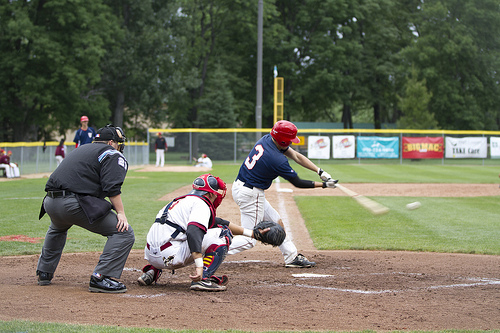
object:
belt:
[43, 182, 75, 199]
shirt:
[144, 192, 213, 253]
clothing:
[37, 143, 135, 276]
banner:
[445, 135, 488, 162]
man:
[37, 126, 132, 294]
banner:
[331, 135, 356, 160]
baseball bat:
[329, 178, 389, 215]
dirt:
[2, 245, 498, 330]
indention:
[235, 290, 293, 312]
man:
[225, 120, 340, 269]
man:
[72, 115, 99, 147]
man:
[153, 133, 169, 168]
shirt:
[73, 124, 104, 145]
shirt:
[153, 138, 169, 148]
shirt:
[43, 140, 130, 198]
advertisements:
[307, 134, 490, 161]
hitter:
[233, 119, 335, 270]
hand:
[321, 179, 338, 188]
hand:
[321, 170, 336, 183]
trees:
[3, 0, 244, 131]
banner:
[401, 137, 442, 161]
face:
[212, 183, 227, 203]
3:
[244, 141, 264, 170]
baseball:
[408, 200, 422, 210]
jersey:
[237, 135, 296, 190]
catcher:
[138, 173, 272, 291]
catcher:
[248, 218, 286, 246]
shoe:
[283, 252, 315, 270]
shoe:
[190, 275, 227, 291]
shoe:
[136, 265, 162, 284]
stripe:
[255, 189, 260, 228]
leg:
[224, 199, 268, 257]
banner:
[354, 136, 402, 159]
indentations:
[85, 294, 116, 304]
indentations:
[129, 308, 166, 319]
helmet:
[270, 120, 299, 148]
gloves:
[316, 168, 339, 184]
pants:
[36, 190, 134, 279]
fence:
[2, 125, 500, 174]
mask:
[212, 177, 228, 207]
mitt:
[251, 217, 289, 247]